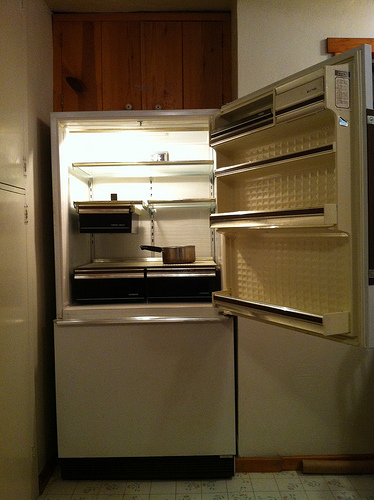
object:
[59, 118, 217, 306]
refrigerator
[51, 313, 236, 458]
freezer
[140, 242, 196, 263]
pan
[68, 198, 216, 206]
drawers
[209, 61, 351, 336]
door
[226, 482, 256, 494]
flooring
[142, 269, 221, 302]
drawer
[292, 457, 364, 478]
tube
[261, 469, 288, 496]
floor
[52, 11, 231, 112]
cabinets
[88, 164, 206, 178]
shelf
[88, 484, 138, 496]
flower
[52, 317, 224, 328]
handle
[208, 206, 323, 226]
hinges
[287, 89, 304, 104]
butter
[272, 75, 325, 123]
compartment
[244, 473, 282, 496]
tiles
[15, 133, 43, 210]
trim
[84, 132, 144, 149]
light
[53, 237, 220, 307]
fridge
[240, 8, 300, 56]
wall